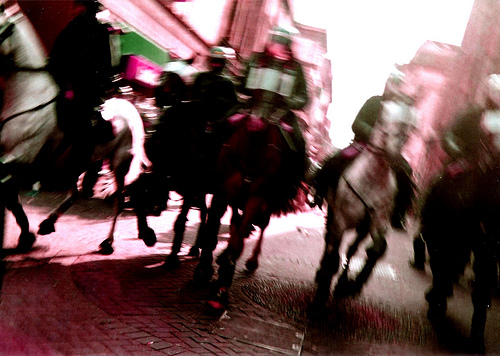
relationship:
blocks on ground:
[205, 279, 319, 356] [24, 203, 489, 347]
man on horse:
[230, 19, 307, 134] [0, 0, 157, 255]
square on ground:
[222, 310, 304, 355] [24, 203, 489, 347]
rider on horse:
[69, 6, 136, 100] [7, 64, 156, 223]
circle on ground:
[69, 236, 204, 355] [24, 203, 489, 347]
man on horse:
[230, 19, 307, 134] [209, 95, 314, 272]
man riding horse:
[230, 19, 307, 134] [0, 0, 157, 255]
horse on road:
[0, 0, 157, 255] [0, 206, 500, 355]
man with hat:
[230, 19, 307, 134] [270, 24, 288, 43]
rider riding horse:
[45, 0, 137, 167] [7, 64, 156, 223]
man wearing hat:
[250, 19, 300, 134] [267, 24, 295, 48]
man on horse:
[250, 19, 300, 134] [209, 95, 314, 272]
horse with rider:
[7, 64, 156, 223] [69, 6, 136, 100]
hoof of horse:
[190, 266, 212, 286] [209, 95, 314, 272]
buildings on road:
[381, 7, 488, 164] [0, 206, 500, 355]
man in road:
[230, 19, 307, 134] [0, 206, 500, 355]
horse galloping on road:
[209, 95, 314, 272] [24, 196, 473, 343]